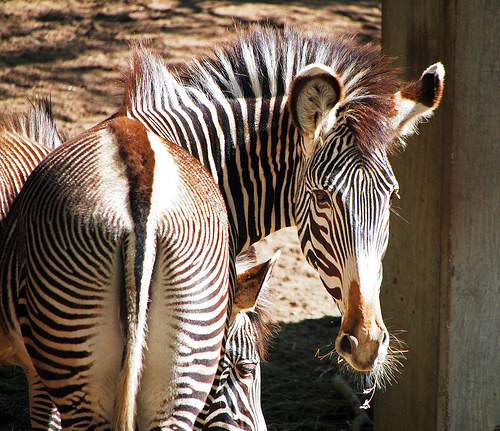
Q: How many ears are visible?
A: 2.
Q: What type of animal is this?
A: Zebra.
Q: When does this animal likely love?
A: Zoo.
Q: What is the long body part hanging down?
A: Tail.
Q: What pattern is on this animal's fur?
A: Stripes.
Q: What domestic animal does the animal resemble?
A: Horse.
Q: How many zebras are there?
A: 2.